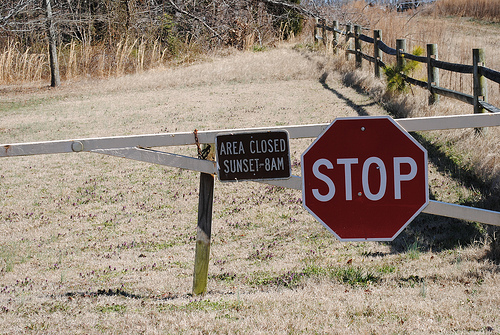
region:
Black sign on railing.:
[208, 115, 267, 202]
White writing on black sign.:
[218, 120, 310, 220]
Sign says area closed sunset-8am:
[190, 135, 287, 258]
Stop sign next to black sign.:
[316, 122, 453, 302]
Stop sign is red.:
[298, 89, 448, 280]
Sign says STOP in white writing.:
[278, 126, 395, 296]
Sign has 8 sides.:
[307, 95, 404, 328]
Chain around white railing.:
[93, 124, 426, 296]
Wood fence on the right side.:
[346, 17, 421, 112]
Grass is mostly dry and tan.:
[70, 222, 202, 317]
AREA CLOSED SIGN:
[209, 131, 291, 184]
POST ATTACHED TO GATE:
[186, 130, 215, 298]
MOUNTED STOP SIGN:
[296, 120, 428, 247]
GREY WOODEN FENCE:
[311, 14, 365, 66]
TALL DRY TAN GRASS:
[2, 44, 47, 84]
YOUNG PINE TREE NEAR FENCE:
[383, 50, 420, 94]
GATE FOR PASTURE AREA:
[0, 114, 499, 303]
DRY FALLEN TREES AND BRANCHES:
[131, 1, 232, 45]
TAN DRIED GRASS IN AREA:
[68, 100, 277, 117]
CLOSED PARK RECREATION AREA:
[3, 3, 494, 333]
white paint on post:
[181, 208, 242, 264]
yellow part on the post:
[167, 243, 239, 313]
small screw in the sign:
[355, 117, 386, 138]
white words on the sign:
[304, 151, 442, 207]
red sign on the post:
[284, 111, 439, 278]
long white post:
[49, 97, 477, 167]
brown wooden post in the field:
[405, 27, 449, 119]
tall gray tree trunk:
[35, 30, 93, 95]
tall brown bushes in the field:
[92, 23, 137, 98]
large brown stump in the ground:
[220, 15, 275, 66]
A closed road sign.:
[211, 110, 306, 195]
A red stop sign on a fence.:
[298, 111, 442, 258]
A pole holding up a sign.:
[174, 129, 227, 303]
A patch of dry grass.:
[260, 261, 304, 301]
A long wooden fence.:
[303, 13, 493, 149]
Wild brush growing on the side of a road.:
[92, 28, 153, 74]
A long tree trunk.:
[27, 8, 68, 101]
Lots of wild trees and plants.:
[121, 18, 268, 35]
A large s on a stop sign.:
[311, 147, 334, 215]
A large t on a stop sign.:
[333, 148, 359, 220]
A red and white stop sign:
[268, 105, 474, 252]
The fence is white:
[26, 102, 491, 277]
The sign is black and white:
[208, 107, 306, 217]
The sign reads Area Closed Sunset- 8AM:
[208, 97, 310, 219]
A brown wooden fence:
[297, 2, 492, 153]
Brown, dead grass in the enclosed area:
[32, 75, 472, 317]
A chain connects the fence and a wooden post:
[163, 107, 232, 203]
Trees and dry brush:
[4, 0, 269, 65]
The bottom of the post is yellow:
[154, 117, 249, 309]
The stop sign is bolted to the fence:
[242, 87, 474, 282]